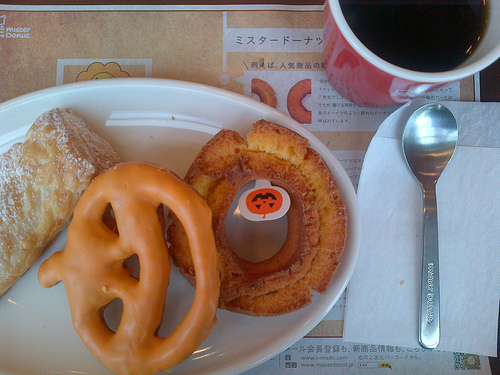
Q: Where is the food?
A: Plate.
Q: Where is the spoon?
A: Side of plate.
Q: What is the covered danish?
A: Cream puff.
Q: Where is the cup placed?
A: Front of spoon.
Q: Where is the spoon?
A: Right of plate.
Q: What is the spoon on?
A: Napkin.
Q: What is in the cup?
A: Drink.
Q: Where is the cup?
A: Table.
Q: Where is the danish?
A: On plate.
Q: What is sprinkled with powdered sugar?
A: Danish.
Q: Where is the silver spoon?
A: On a napkin.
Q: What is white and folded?
A: The napkin.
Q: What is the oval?
A: A white plate.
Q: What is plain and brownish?
A: Donuts.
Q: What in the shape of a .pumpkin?
A: A pretzel.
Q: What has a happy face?
A: The pretzel.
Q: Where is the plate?
A: Near the red cup.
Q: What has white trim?
A: The cup.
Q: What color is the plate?
A: White.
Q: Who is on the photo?
A: No one.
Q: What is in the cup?
A: Coffee.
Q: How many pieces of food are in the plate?
A: Three.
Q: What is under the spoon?
A: Napkin.